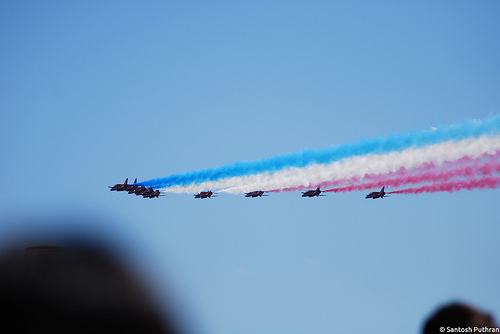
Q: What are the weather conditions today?
A: It is cloudless.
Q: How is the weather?
A: It is cloudless.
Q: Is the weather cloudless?
A: Yes, it is cloudless.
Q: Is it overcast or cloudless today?
A: It is cloudless.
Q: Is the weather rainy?
A: No, it is cloudless.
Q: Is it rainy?
A: No, it is cloudless.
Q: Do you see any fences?
A: No, there are no fences.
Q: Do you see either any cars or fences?
A: No, there are no fences or cars.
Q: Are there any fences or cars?
A: No, there are no fences or cars.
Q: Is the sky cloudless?
A: Yes, the sky is cloudless.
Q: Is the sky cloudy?
A: No, the sky is cloudless.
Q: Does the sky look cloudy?
A: No, the sky is cloudless.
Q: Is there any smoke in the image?
A: Yes, there is smoke.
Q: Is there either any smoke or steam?
A: Yes, there is smoke.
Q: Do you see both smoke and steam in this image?
A: No, there is smoke but no steam.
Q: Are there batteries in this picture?
A: No, there are no batteries.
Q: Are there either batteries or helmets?
A: No, there are no batteries or helmets.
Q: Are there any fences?
A: No, there are no fences.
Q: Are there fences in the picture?
A: No, there are no fences.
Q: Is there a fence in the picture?
A: No, there are no fences.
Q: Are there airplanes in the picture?
A: Yes, there are airplanes.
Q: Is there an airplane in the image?
A: Yes, there are airplanes.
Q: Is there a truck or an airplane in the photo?
A: Yes, there are airplanes.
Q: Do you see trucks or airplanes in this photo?
A: Yes, there are airplanes.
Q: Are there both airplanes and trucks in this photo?
A: No, there are airplanes but no trucks.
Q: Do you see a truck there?
A: No, there are no trucks.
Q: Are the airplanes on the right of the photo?
A: Yes, the airplanes are on the right of the image.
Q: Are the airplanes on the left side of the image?
A: No, the airplanes are on the right of the image.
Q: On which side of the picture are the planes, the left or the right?
A: The planes are on the right of the image.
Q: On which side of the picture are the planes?
A: The planes are on the right of the image.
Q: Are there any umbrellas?
A: No, there are no umbrellas.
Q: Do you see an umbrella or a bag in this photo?
A: No, there are no umbrellas or bags.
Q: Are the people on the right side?
A: Yes, the people are on the right of the image.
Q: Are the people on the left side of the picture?
A: No, the people are on the right of the image.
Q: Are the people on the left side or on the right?
A: The people are on the right of the image.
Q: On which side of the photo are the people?
A: The people are on the right of the image.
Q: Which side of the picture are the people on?
A: The people are on the right of the image.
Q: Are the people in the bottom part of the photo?
A: Yes, the people are in the bottom of the image.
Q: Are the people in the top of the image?
A: No, the people are in the bottom of the image.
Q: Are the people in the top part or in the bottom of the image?
A: The people are in the bottom of the image.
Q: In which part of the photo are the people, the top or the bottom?
A: The people are in the bottom of the image.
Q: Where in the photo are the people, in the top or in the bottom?
A: The people are in the bottom of the image.